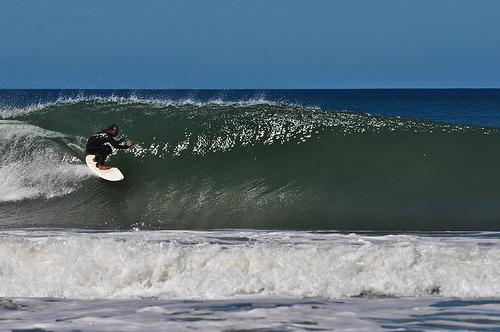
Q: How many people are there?
A: One.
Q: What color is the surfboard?
A: White.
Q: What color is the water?
A: Gray.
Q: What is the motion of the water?
A: Wavy.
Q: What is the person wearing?
A: Wetsuit.